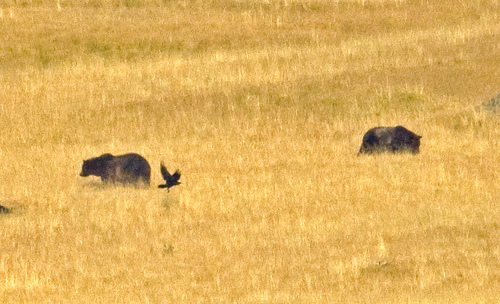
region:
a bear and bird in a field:
[77, 150, 184, 195]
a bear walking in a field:
[80, 154, 152, 188]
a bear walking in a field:
[355, 124, 421, 159]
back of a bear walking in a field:
[357, 120, 421, 157]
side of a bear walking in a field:
[78, 152, 150, 187]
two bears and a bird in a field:
[76, 121, 421, 197]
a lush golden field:
[3, 1, 498, 116]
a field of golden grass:
[1, 193, 495, 300]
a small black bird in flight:
[155, 161, 182, 189]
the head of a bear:
[78, 157, 93, 176]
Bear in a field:
[47, 140, 164, 194]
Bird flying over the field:
[155, 157, 186, 197]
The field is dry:
[187, 56, 315, 192]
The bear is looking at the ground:
[337, 107, 465, 177]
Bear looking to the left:
[67, 130, 97, 180]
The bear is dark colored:
[342, 103, 429, 158]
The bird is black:
[150, 155, 181, 195]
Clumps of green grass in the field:
[75, 29, 170, 66]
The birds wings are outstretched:
[150, 151, 185, 191]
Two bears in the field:
[66, 124, 460, 180]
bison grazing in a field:
[351, 118, 430, 161]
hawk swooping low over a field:
[152, 159, 190, 192]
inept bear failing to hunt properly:
[72, 148, 153, 192]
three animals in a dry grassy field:
[17, 65, 484, 298]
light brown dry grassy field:
[208, 79, 333, 254]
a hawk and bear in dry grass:
[74, 133, 195, 198]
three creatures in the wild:
[70, 96, 430, 202]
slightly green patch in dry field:
[308, 71, 435, 111]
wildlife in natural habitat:
[61, 53, 442, 218]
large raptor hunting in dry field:
[153, 154, 203, 208]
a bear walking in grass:
[80, 150, 152, 187]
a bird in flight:
[155, 161, 187, 190]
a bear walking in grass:
[357, 122, 422, 158]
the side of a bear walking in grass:
[78, 149, 149, 189]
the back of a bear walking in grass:
[361, 123, 423, 160]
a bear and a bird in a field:
[75, 141, 185, 197]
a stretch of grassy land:
[1, 0, 497, 120]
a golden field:
[2, 201, 497, 302]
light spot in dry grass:
[286, 37, 337, 80]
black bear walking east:
[338, 107, 416, 164]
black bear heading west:
[80, 146, 130, 198]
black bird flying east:
[153, 151, 185, 196]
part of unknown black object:
[5, 169, 27, 236]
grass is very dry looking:
[408, 237, 458, 257]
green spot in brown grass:
[361, 76, 427, 118]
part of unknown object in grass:
[473, 93, 498, 131]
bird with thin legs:
[165, 186, 180, 196]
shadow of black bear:
[85, 178, 115, 202]